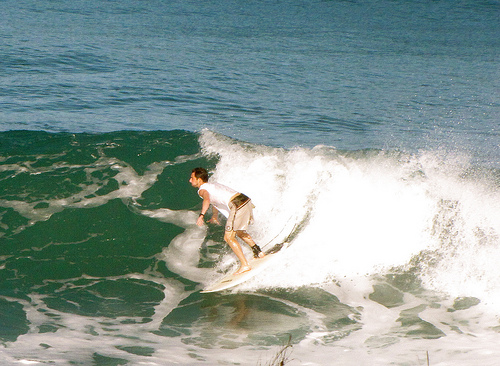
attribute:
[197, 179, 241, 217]
shirt — white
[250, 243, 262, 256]
black cable — black 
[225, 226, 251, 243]
knees — Surfer's, bent , balance 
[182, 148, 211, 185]
surfer — head 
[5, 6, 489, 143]
sea — Blue 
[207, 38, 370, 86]
water — vast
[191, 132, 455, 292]
wake — white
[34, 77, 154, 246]
water — blue green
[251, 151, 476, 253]
wave — toppling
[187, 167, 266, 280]
man — surfing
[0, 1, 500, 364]
water — calm , blue 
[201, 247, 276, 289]
board — white  